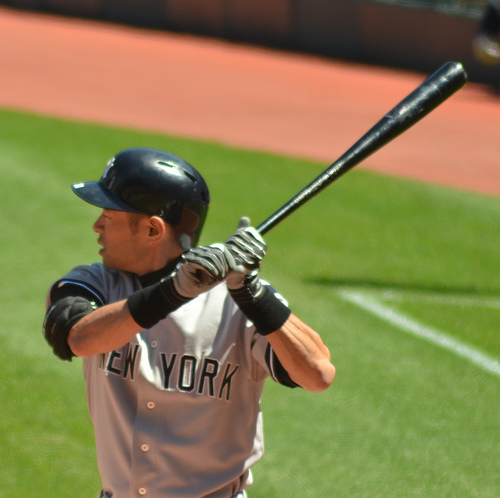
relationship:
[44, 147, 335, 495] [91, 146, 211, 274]
player has head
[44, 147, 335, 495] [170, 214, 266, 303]
player has gloves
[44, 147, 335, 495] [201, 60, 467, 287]
player has bat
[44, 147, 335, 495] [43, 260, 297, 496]
player in outfit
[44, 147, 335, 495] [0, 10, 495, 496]
player in field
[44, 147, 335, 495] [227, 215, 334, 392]
player has hand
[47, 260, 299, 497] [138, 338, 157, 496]
shirt has buttons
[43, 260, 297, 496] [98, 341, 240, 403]
outfit has embriodery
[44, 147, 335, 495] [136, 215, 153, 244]
player has sideburns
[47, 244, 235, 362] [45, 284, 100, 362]
arm has brace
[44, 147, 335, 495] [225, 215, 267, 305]
player has glove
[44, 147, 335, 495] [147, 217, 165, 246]
player has ear